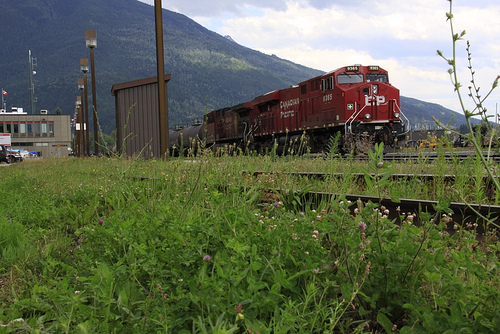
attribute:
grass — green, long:
[21, 175, 259, 300]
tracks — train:
[99, 156, 491, 229]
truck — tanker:
[171, 107, 209, 147]